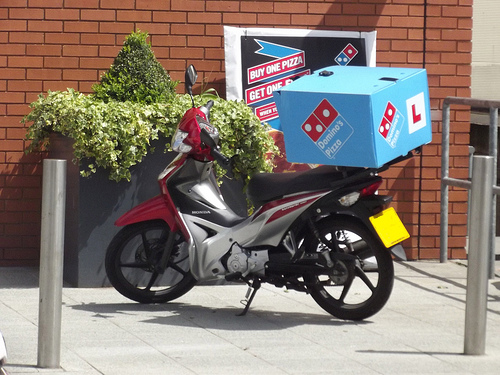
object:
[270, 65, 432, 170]
box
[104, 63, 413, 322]
motorcycle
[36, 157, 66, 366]
post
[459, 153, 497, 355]
post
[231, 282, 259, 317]
kickstand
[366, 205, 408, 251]
plate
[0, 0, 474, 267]
wall